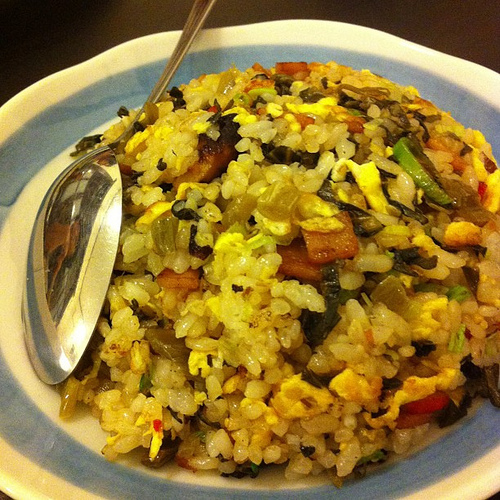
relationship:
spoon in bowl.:
[22, 2, 215, 385] [0, 19, 499, 499]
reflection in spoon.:
[17, 147, 123, 386] [22, 2, 215, 385]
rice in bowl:
[57, 60, 500, 490] [0, 19, 499, 499]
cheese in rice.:
[137, 179, 214, 224] [57, 60, 500, 490]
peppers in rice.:
[392, 138, 457, 208] [57, 60, 500, 490]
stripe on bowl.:
[1, 40, 500, 234] [0, 19, 499, 499]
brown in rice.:
[303, 214, 360, 263] [57, 60, 500, 490]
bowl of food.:
[0, 19, 499, 499] [57, 60, 500, 490]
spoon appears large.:
[22, 2, 215, 385] [19, 146, 124, 385]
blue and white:
[1, 40, 500, 234] [1, 16, 500, 143]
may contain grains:
[145, 325, 194, 378] [207, 246, 364, 476]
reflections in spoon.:
[17, 147, 123, 386] [22, 2, 215, 385]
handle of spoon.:
[108, 1, 217, 151] [22, 2, 215, 385]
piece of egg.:
[188, 348, 219, 379] [187, 350, 214, 378]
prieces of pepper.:
[389, 137, 451, 204] [392, 138, 457, 208]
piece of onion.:
[144, 323, 197, 382] [142, 326, 192, 379]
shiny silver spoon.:
[19, 1, 216, 387] [22, 2, 215, 385]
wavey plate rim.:
[1, 18, 499, 163] [1, 19, 500, 163]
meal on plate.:
[54, 59, 499, 488] [0, 19, 499, 499]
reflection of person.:
[17, 147, 123, 386] [41, 212, 83, 311]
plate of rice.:
[0, 19, 499, 499] [57, 60, 500, 490]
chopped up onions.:
[147, 328, 204, 382] [144, 325, 199, 384]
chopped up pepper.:
[393, 132, 457, 206] [392, 138, 457, 208]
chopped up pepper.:
[398, 393, 450, 416] [400, 388, 450, 418]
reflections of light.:
[17, 147, 123, 386] [67, 200, 122, 356]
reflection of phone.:
[17, 147, 123, 386] [41, 213, 83, 267]